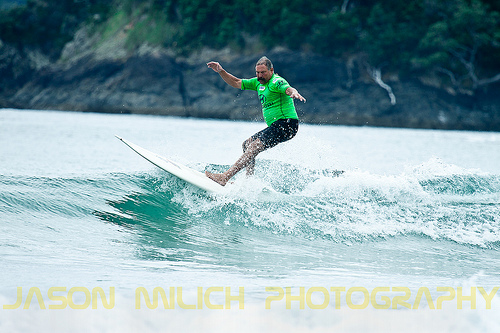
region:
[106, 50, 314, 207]
A man on a surfboard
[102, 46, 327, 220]
A man surfing in the ocean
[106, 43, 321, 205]
A man catching a wave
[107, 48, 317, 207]
A man standing on a surfboard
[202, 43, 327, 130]
A man wearing a green shirt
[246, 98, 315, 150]
A man wearing black shorts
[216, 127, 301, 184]
Water spraying in the air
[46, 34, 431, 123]
A rocky cliff behind the man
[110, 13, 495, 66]
Trees on the rocky cliff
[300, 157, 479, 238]
A wave in the ocean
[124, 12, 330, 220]
man surfing in the ocean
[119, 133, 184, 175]
a white surfboard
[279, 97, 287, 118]
black stripe on a green shirt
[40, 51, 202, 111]
a rocky hill near the sea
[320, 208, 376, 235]
white foam on the surface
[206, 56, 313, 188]
a man wearing a green shirt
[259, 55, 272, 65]
wet brown hair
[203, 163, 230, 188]
bare feet on a surfboard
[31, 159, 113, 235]
clear aqua blue sea water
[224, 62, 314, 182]
a man wearing blue shorts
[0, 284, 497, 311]
The photographer of the image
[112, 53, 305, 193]
a surfer on a surfboard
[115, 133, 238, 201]
a white surfboard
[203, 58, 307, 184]
a surfer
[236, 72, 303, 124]
a green shirt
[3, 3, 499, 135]
mountains emerging from water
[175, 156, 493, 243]
a wave in a body of water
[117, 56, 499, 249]
A surfer riding a wave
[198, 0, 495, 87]
shrubs on a mountain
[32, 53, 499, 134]
exposed rock on a mountain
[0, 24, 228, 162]
man surfing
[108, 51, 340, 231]
man surfing in ocean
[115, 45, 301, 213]
man surfing in green and white ocean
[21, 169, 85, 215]
green and white ocean waves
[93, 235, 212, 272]
green and white ocean waves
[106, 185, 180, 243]
green and white ocean waves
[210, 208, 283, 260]
green and white ocean waves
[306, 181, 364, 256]
green and white ocean waves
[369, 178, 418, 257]
green and white ocean waves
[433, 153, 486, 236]
green and white ocean waves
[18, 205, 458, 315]
The water in the ocean is blue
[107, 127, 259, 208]
The surfboard is white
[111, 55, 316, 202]
The man is surfing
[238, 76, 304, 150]
The man is wearing a wet suit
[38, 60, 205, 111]
There is a large boulder of rocks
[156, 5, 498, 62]
The bushes on the mountains are green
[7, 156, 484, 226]
A wave in the ocean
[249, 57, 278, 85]
The head of the surfer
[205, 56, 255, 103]
The arm of the surfer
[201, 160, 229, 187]
The foot of the surfer